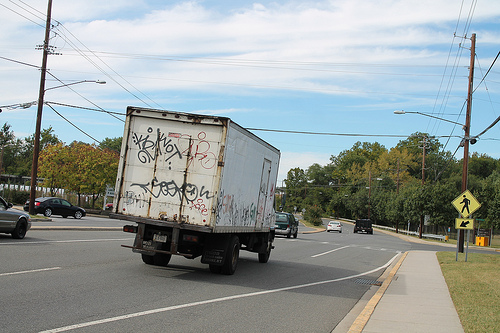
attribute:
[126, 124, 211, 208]
graffiti — white, red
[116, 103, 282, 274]
truck — white, black, moving, vandalized, large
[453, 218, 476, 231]
sign — yellow, indicatiing, black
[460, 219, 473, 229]
arrow — black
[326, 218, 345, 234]
car — white, small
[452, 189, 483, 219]
sign — black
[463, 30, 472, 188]
pole — electrical, wooden, electric, leaning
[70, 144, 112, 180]
tree — green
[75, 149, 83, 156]
leaves — green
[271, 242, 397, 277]
street — busy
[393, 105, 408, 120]
streetlight — off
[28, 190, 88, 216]
car — black, compact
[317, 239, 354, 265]
line — whtie, white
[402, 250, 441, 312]
sidewalk — grey, cement, concrete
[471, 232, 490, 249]
object — orange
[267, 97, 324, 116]
sky — blue, white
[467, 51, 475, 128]
post — electrical, wooden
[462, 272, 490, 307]
grass — green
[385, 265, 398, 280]
line — yellow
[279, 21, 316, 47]
clouds — white